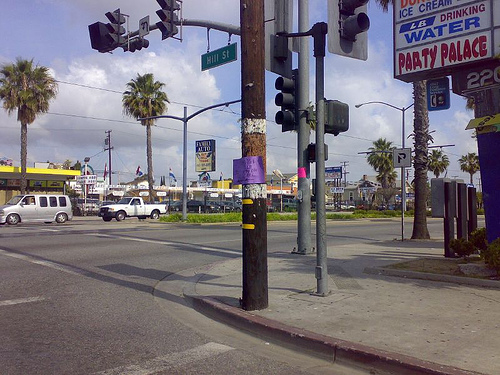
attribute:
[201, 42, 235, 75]
sign — green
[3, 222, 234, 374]
street — slow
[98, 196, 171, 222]
truck — white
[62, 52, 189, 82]
sky — cloudy, blue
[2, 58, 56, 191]
tree — green, tall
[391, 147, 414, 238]
sign — metal, black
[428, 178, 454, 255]
telephone — grey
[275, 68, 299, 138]
light — black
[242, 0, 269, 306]
pole — wooden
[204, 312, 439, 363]
sidewalk — tan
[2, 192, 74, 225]
van — silver, big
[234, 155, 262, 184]
flyer — purple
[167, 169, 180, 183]
flag — flying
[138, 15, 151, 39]
directional sign — white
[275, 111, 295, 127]
light — round, dark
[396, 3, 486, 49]
logo — big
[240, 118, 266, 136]
paint — white